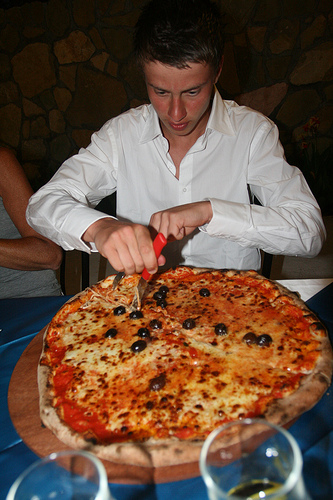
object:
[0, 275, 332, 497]
table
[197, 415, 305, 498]
glass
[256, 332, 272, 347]
olives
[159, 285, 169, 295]
olives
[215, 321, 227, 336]
olives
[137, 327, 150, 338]
olives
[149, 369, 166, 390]
olives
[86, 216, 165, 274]
left hand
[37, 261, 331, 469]
pizza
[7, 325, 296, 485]
board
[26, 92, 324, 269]
shirt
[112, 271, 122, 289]
fork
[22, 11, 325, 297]
man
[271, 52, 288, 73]
stone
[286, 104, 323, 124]
stone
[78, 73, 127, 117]
stone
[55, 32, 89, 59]
stone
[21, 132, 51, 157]
stone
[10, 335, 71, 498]
wooden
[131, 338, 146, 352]
olives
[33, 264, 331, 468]
crust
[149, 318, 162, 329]
olives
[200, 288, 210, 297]
olives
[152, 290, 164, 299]
olives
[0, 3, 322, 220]
wall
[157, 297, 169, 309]
olive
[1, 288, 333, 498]
tablecloth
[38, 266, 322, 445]
cheese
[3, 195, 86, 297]
chair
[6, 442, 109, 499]
glass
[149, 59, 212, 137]
face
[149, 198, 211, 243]
left hand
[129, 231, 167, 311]
knife